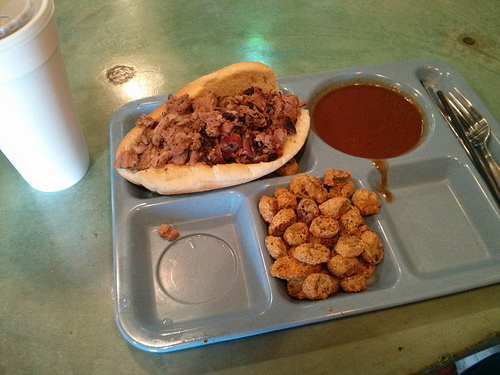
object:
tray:
[99, 55, 499, 349]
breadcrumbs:
[289, 192, 366, 279]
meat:
[213, 107, 285, 137]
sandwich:
[104, 62, 310, 199]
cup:
[0, 2, 92, 196]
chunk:
[180, 104, 259, 163]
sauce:
[309, 81, 430, 158]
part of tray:
[136, 243, 239, 321]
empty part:
[399, 169, 483, 279]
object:
[69, 9, 181, 86]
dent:
[104, 62, 137, 86]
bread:
[141, 169, 241, 182]